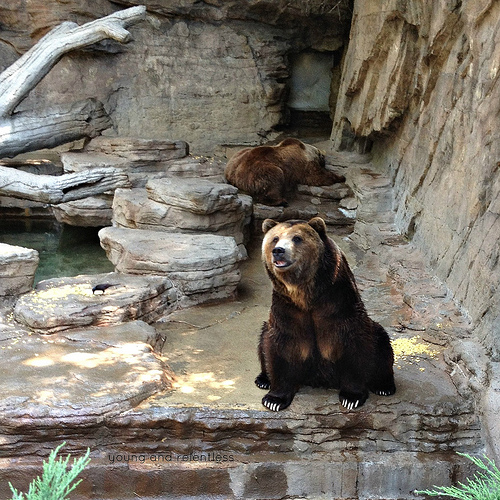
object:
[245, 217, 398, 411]
bear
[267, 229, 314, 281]
face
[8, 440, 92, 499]
plant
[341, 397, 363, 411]
claws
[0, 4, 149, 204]
wood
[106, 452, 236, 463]
text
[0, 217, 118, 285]
water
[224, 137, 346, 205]
bear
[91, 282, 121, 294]
bird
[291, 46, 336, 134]
cave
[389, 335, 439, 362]
food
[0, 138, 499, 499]
rocks